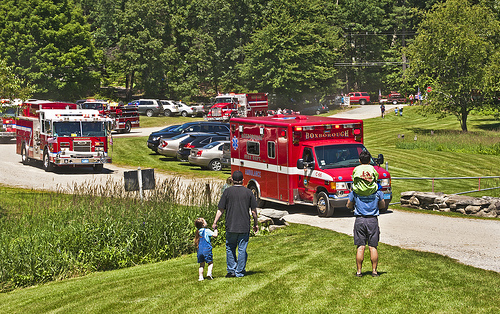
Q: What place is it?
A: It is a field.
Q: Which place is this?
A: It is a field.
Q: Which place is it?
A: It is a field.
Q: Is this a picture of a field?
A: Yes, it is showing a field.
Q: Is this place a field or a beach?
A: It is a field.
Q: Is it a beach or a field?
A: It is a field.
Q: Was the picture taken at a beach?
A: No, the picture was taken in a field.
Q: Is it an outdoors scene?
A: Yes, it is outdoors.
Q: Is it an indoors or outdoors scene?
A: It is outdoors.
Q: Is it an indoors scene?
A: No, it is outdoors.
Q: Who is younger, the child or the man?
A: The child is younger than the man.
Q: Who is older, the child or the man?
A: The man is older than the child.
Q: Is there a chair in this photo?
A: No, there are no chairs.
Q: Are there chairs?
A: No, there are no chairs.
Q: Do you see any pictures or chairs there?
A: No, there are no chairs or pictures.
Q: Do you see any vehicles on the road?
A: Yes, there is a vehicle on the road.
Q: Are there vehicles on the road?
A: Yes, there is a vehicle on the road.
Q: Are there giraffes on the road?
A: No, there is a vehicle on the road.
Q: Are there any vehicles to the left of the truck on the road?
A: No, the vehicle is to the right of the truck.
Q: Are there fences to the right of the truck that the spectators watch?
A: No, there is a vehicle to the right of the truck.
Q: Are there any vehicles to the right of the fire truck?
A: Yes, there is a vehicle to the right of the fire truck.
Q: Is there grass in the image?
A: Yes, there is grass.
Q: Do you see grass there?
A: Yes, there is grass.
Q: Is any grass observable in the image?
A: Yes, there is grass.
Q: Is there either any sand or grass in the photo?
A: Yes, there is grass.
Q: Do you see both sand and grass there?
A: No, there is grass but no sand.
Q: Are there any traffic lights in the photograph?
A: No, there are no traffic lights.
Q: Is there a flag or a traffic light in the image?
A: No, there are no traffic lights or flags.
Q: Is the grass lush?
A: Yes, the grass is lush.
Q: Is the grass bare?
A: No, the grass is lush.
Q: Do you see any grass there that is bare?
A: No, there is grass but it is lush.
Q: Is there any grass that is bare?
A: No, there is grass but it is lush.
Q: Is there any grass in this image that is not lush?
A: No, there is grass but it is lush.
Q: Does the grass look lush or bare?
A: The grass is lush.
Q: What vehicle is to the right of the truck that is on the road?
A: The vehicle is a car.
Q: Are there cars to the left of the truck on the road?
A: No, the car is to the right of the truck.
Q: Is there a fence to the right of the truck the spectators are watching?
A: No, there is a car to the right of the truck.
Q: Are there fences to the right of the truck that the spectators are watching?
A: No, there is a car to the right of the truck.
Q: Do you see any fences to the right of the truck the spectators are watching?
A: No, there is a car to the right of the truck.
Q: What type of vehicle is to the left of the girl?
A: The vehicle is a car.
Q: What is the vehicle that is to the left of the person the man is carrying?
A: The vehicle is a car.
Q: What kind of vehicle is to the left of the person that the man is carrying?
A: The vehicle is a car.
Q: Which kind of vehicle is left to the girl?
A: The vehicle is a car.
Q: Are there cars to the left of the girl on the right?
A: Yes, there is a car to the left of the girl.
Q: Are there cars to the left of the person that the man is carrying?
A: Yes, there is a car to the left of the girl.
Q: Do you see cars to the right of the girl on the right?
A: No, the car is to the left of the girl.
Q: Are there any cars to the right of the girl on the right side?
A: No, the car is to the left of the girl.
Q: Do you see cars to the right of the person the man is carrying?
A: No, the car is to the left of the girl.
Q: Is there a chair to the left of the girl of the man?
A: No, there is a car to the left of the girl.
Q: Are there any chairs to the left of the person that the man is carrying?
A: No, there is a car to the left of the girl.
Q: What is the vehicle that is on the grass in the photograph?
A: The vehicle is a car.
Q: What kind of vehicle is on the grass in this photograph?
A: The vehicle is a car.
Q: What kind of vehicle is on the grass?
A: The vehicle is a car.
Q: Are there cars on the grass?
A: Yes, there is a car on the grass.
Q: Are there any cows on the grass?
A: No, there is a car on the grass.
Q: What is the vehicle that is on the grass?
A: The vehicle is a car.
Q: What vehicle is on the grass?
A: The vehicle is a car.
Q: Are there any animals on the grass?
A: No, there is a car on the grass.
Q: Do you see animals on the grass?
A: No, there is a car on the grass.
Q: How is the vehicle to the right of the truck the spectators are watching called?
A: The vehicle is a car.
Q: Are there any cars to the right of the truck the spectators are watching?
A: Yes, there is a car to the right of the truck.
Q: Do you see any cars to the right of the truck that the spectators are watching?
A: Yes, there is a car to the right of the truck.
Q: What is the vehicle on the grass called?
A: The vehicle is a car.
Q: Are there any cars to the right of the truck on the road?
A: Yes, there is a car to the right of the truck.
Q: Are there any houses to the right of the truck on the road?
A: No, there is a car to the right of the truck.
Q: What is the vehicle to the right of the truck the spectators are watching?
A: The vehicle is a car.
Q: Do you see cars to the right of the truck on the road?
A: Yes, there is a car to the right of the truck.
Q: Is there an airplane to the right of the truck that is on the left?
A: No, there is a car to the right of the truck.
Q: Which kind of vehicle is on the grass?
A: The vehicle is a car.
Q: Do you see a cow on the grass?
A: No, there is a car on the grass.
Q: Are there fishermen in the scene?
A: No, there are no fishermen.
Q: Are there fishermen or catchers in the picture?
A: No, there are no fishermen or catchers.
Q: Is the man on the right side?
A: Yes, the man is on the right of the image.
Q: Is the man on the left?
A: No, the man is on the right of the image.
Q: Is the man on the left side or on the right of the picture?
A: The man is on the right of the image.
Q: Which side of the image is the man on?
A: The man is on the right of the image.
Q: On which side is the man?
A: The man is on the right of the image.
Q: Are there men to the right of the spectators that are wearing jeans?
A: Yes, there is a man to the right of the spectators.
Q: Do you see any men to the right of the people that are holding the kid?
A: Yes, there is a man to the right of the spectators.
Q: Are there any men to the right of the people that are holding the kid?
A: Yes, there is a man to the right of the spectators.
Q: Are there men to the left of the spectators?
A: No, the man is to the right of the spectators.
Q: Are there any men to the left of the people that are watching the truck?
A: No, the man is to the right of the spectators.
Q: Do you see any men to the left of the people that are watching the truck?
A: No, the man is to the right of the spectators.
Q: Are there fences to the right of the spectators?
A: No, there is a man to the right of the spectators.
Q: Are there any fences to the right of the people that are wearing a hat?
A: No, there is a man to the right of the spectators.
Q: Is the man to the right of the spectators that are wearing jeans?
A: Yes, the man is to the right of the spectators.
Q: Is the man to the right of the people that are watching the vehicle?
A: Yes, the man is to the right of the spectators.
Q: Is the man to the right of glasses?
A: No, the man is to the right of the spectators.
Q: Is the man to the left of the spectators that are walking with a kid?
A: No, the man is to the right of the spectators.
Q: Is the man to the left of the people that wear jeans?
A: No, the man is to the right of the spectators.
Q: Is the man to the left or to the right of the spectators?
A: The man is to the right of the spectators.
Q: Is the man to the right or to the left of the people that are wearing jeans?
A: The man is to the right of the spectators.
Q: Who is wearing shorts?
A: The man is wearing shorts.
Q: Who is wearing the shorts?
A: The man is wearing shorts.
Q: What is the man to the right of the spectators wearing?
A: The man is wearing shorts.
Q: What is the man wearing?
A: The man is wearing shorts.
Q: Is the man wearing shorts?
A: Yes, the man is wearing shorts.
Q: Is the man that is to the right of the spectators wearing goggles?
A: No, the man is wearing shorts.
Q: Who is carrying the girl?
A: The man is carrying the girl.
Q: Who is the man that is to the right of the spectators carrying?
A: The man is carrying a girl.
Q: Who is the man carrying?
A: The man is carrying a girl.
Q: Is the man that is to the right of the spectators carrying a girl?
A: Yes, the man is carrying a girl.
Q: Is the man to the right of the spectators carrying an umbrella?
A: No, the man is carrying a girl.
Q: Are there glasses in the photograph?
A: No, there are no glasses.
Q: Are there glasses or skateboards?
A: No, there are no glasses or skateboards.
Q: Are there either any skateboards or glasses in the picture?
A: No, there are no glasses or skateboards.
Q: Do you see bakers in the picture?
A: No, there are no bakers.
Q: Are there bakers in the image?
A: No, there are no bakers.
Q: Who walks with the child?
A: The spectators walk with the child.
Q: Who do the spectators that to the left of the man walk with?
A: The spectators walk with a kid.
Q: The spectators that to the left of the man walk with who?
A: The spectators walk with a kid.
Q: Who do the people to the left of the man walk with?
A: The spectators walk with a kid.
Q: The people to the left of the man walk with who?
A: The spectators walk with a kid.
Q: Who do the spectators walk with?
A: The spectators walk with a kid.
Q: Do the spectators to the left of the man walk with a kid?
A: Yes, the spectators walk with a kid.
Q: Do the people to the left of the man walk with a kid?
A: Yes, the spectators walk with a kid.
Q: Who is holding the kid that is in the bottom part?
A: The spectators are holding the child.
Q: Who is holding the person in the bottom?
A: The spectators are holding the child.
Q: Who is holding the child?
A: The spectators are holding the child.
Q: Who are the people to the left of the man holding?
A: The spectators are holding the child.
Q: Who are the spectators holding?
A: The spectators are holding the child.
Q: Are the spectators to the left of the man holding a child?
A: Yes, the spectators are holding a child.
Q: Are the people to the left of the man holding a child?
A: Yes, the spectators are holding a child.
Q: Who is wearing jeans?
A: The spectators are wearing jeans.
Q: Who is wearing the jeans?
A: The spectators are wearing jeans.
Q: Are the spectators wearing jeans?
A: Yes, the spectators are wearing jeans.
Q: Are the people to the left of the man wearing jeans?
A: Yes, the spectators are wearing jeans.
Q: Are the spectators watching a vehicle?
A: Yes, the spectators are watching a vehicle.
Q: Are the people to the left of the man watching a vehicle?
A: Yes, the spectators are watching a vehicle.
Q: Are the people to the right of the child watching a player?
A: No, the spectators are watching a vehicle.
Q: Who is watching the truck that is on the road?
A: The spectators are watching the truck.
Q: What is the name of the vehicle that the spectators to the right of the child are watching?
A: The vehicle is a truck.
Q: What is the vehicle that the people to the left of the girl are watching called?
A: The vehicle is a truck.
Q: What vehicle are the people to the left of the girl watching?
A: The spectators are watching the truck.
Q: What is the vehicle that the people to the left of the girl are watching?
A: The vehicle is a truck.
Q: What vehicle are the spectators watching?
A: The spectators are watching the truck.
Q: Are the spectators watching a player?
A: No, the spectators are watching the truck.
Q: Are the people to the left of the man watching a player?
A: No, the spectators are watching the truck.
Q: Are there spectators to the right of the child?
A: Yes, there are spectators to the right of the child.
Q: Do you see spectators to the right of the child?
A: Yes, there are spectators to the right of the child.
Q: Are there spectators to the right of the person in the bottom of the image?
A: Yes, there are spectators to the right of the child.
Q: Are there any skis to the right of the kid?
A: No, there are spectators to the right of the kid.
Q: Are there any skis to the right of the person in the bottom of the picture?
A: No, there are spectators to the right of the kid.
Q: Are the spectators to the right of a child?
A: Yes, the spectators are to the right of a child.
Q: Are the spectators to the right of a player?
A: No, the spectators are to the right of a child.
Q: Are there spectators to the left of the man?
A: Yes, there are spectators to the left of the man.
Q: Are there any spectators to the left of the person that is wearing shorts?
A: Yes, there are spectators to the left of the man.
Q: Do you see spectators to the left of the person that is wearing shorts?
A: Yes, there are spectators to the left of the man.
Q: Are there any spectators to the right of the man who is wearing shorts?
A: No, the spectators are to the left of the man.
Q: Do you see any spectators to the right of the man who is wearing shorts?
A: No, the spectators are to the left of the man.